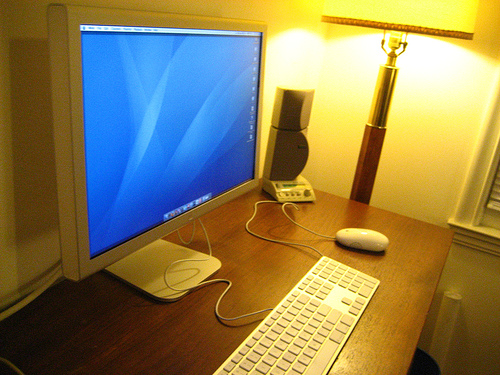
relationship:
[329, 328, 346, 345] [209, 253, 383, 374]
button on top of keyboard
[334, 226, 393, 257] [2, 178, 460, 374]
mouse on top of desk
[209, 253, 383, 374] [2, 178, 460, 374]
keyboard on top of desk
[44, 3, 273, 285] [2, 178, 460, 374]
monitor on top of desk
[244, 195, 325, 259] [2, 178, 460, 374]
cord on top of desk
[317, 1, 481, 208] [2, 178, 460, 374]
lamp next to desk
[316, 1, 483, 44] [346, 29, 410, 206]
lamp shade on top of lamp pole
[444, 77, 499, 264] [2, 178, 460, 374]
window next to desk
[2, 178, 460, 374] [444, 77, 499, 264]
desk next to window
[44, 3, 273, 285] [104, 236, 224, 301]
monitor has stand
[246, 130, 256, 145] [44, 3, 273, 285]
icon on monitor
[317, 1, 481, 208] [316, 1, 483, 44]
lamp has lamp shade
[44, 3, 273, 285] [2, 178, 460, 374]
monitor sitting on desk